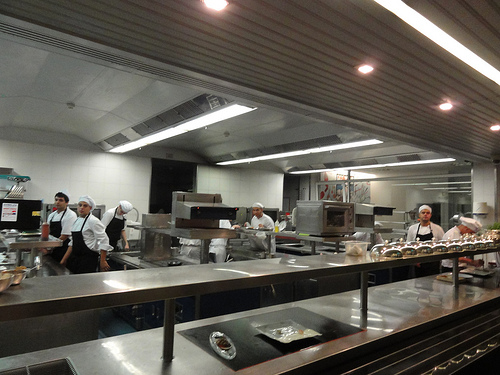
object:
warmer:
[167, 181, 237, 233]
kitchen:
[0, 0, 499, 375]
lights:
[101, 101, 253, 156]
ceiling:
[0, 18, 500, 174]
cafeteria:
[0, 0, 499, 374]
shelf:
[117, 243, 494, 364]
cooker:
[58, 195, 107, 275]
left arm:
[93, 220, 114, 270]